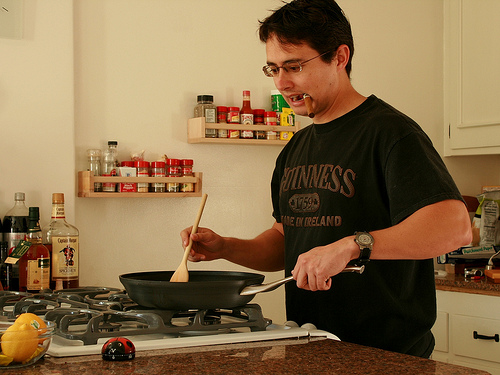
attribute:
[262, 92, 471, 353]
t-shirt — black, Guiness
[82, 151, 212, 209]
rack — wood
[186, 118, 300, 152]
spice rack — wooden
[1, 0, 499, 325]
wall — white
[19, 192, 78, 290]
bottles — glass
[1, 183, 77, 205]
bottles — large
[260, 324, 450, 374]
counter top — brown, granite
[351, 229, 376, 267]
watch — black, silver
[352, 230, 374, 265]
watch — black, grey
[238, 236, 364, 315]
handle — silver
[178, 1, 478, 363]
man — cooking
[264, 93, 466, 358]
shirt — dark green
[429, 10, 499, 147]
cabinets — white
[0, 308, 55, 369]
bowl — glass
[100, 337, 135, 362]
ladybug — timer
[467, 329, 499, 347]
handle — black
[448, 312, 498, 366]
cabinet — white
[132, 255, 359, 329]
frying pan — large, black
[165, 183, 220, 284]
spoon — wooden, light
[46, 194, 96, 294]
bottle — glass, liquor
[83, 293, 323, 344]
range — gas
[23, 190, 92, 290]
liquor — bottles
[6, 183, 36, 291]
bottle — soda